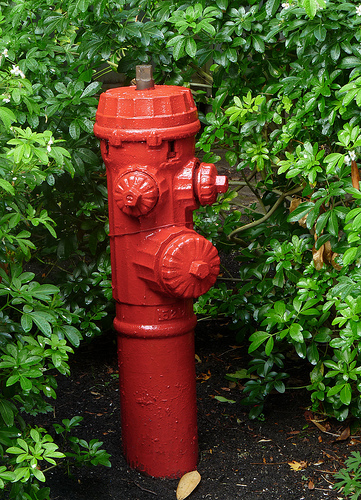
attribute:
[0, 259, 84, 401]
leaves — wet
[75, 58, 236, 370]
hydrant — red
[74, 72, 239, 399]
fire hydrant — red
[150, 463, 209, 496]
leaf — dry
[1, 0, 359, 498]
bushes — green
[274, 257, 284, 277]
leaf — wet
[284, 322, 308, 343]
leaf — wet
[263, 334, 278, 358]
leaf — wet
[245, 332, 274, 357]
leaf — wet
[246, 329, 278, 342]
leaf — wet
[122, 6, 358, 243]
bush — green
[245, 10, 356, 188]
leaves — green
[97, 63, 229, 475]
hydrant — bright red, red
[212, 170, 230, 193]
knob — red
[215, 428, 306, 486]
soil — dark brown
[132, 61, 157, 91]
knob — gray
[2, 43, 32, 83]
flowers — white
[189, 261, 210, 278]
knob — red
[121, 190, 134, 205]
knob — red